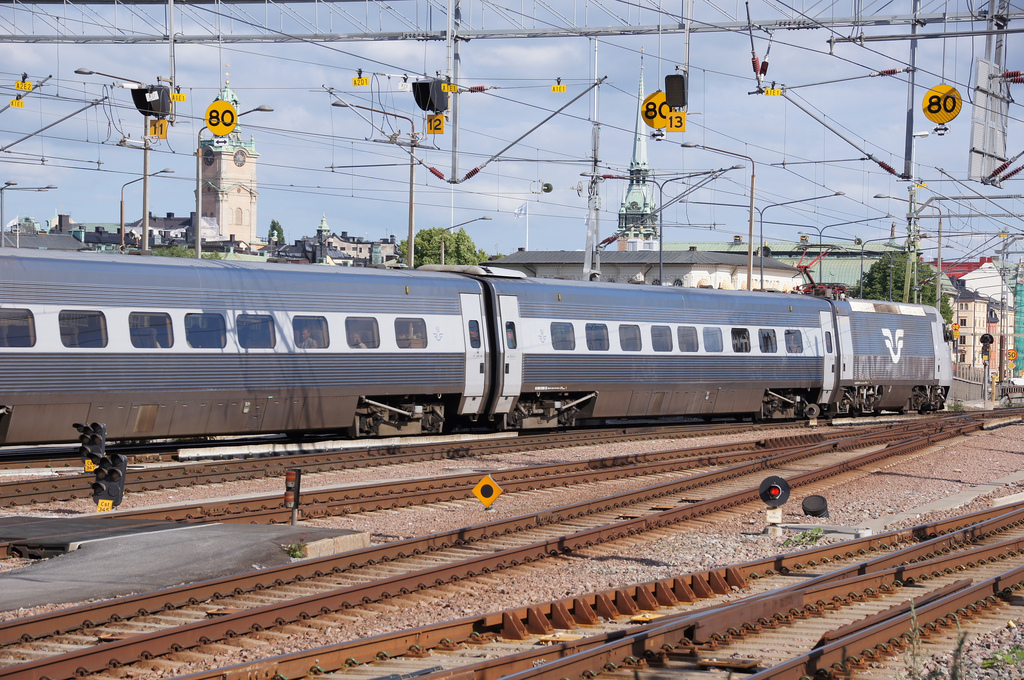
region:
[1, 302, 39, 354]
Window on a train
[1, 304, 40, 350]
Window on a silver train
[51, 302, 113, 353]
Window on a train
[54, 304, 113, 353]
Window on a silver train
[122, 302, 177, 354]
Window on a train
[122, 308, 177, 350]
Window on a silver train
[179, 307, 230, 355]
Window on a train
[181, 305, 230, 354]
Window on a silver train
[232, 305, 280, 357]
Window on a train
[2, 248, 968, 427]
The silver train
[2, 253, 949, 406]
A silver train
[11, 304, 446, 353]
The row of windows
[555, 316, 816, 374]
A row of windows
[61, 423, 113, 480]
The traffic signal on the tracks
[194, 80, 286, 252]
The tall building to the left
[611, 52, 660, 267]
The tall building to the right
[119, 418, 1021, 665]
The rusty train tracks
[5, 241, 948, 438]
silver train cars on tracks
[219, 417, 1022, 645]
tan gravel in between tracks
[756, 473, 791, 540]
red light mounted on concrete post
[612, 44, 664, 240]
pale blue church steeple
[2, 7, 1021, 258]
white puffy clouds in blue sky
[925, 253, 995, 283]
red roof top on building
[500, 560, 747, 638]
orange rust on tracks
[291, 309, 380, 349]
people visible in windows of train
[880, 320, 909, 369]
white logo painted on side of train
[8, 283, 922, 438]
TRAIN IS GREY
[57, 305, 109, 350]
A window on a vehicle.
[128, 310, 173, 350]
A window on a vehicle.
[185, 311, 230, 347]
A window on a vehicle.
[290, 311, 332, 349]
A window on a vehicle.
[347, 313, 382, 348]
A window on a vehicle.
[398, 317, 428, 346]
A window on a vehicle.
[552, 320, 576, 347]
A window on a vehicle.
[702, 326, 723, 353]
A window on a vehicle.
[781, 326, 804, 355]
A window on a vehicle.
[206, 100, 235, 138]
the sign is yellow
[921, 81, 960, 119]
the sign is yellow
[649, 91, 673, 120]
the sign is yellow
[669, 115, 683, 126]
the sign is yellow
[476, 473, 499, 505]
the sign is yellow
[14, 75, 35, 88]
the sign is yellow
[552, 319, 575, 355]
window on the train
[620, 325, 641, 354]
window on the train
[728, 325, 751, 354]
window on the train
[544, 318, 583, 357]
A window on a train.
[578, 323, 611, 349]
A window on a train.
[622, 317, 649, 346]
A window on a train.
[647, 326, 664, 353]
A window on a train.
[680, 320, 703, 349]
A window on a train.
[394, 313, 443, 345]
A window on a train.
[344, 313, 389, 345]
A window on a train.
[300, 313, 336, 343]
A window on a train.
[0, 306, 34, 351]
glass window on train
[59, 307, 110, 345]
glass window on train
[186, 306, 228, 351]
glass window on train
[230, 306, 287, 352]
glass window on train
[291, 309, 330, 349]
glass window on train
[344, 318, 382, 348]
glass window on train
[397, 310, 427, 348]
glass window on train